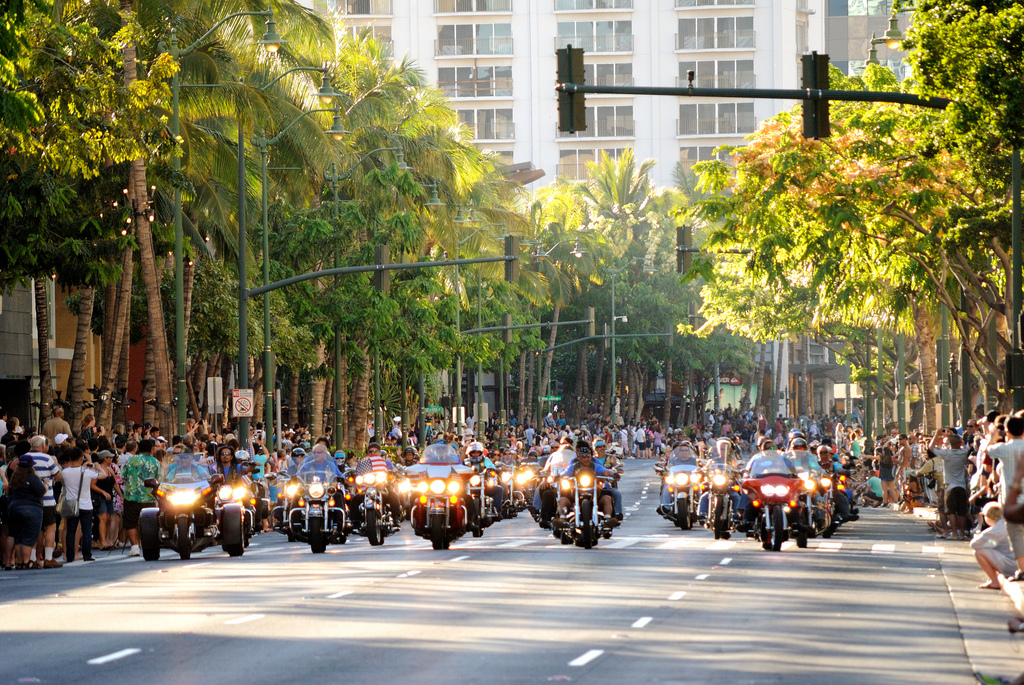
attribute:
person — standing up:
[634, 423, 651, 458]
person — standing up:
[985, 412, 1021, 577]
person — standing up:
[928, 419, 980, 537]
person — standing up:
[890, 428, 919, 506]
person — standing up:
[868, 437, 903, 504]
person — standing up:
[56, 438, 115, 560]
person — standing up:
[21, 425, 72, 574]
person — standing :
[8, 445, 51, 578]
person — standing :
[120, 432, 163, 551]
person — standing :
[41, 410, 76, 464]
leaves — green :
[691, 151, 730, 196]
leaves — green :
[661, 197, 716, 232]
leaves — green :
[831, 292, 876, 337]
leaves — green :
[868, 245, 925, 293]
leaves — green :
[723, 301, 810, 346]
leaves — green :
[828, 346, 861, 375]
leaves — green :
[385, 197, 436, 265]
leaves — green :
[442, 138, 503, 203]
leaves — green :
[582, 138, 621, 200]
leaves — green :
[484, 276, 523, 319]